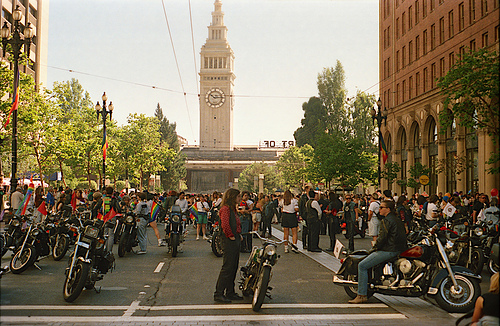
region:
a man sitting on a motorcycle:
[326, 198, 485, 315]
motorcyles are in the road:
[5, 179, 464, 315]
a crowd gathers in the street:
[11, 160, 491, 301]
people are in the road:
[6, 169, 488, 310]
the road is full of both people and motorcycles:
[9, 178, 491, 307]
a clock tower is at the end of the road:
[181, 0, 250, 159]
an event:
[5, 141, 495, 324]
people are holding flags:
[21, 174, 228, 255]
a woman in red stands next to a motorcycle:
[204, 183, 294, 312]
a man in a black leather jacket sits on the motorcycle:
[334, 199, 479, 311]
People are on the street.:
[15, 163, 498, 250]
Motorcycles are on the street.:
[1, 205, 498, 320]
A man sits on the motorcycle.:
[319, 191, 484, 308]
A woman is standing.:
[192, 182, 266, 309]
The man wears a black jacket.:
[363, 207, 416, 257]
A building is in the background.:
[140, 1, 331, 207]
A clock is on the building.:
[190, 79, 230, 116]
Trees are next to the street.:
[0, 55, 400, 214]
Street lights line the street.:
[80, 82, 126, 199]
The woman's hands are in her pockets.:
[217, 220, 254, 253]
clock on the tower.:
[208, 90, 223, 110]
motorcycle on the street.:
[250, 240, 283, 304]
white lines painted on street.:
[142, 299, 198, 316]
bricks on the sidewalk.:
[292, 321, 332, 324]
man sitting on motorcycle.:
[365, 215, 400, 295]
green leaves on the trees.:
[59, 117, 89, 165]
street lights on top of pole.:
[0, 7, 25, 42]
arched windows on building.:
[421, 115, 437, 169]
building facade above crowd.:
[404, 24, 469, 51]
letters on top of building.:
[262, 135, 293, 152]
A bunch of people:
[5, 112, 499, 322]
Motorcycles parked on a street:
[7, 164, 499, 313]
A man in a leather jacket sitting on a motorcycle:
[333, 199, 464, 309]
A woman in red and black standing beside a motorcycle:
[212, 184, 286, 311]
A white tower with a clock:
[192, 4, 250, 163]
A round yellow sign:
[414, 170, 436, 192]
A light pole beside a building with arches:
[365, 12, 440, 196]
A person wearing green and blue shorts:
[192, 192, 212, 248]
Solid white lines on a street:
[0, 293, 384, 324]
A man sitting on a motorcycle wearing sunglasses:
[325, 193, 472, 324]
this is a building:
[193, 15, 239, 150]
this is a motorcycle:
[242, 231, 293, 306]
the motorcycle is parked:
[236, 245, 282, 311]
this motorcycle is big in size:
[58, 217, 123, 299]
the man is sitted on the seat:
[353, 193, 408, 304]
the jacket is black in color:
[378, 217, 400, 251]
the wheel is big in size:
[250, 263, 275, 304]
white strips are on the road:
[144, 292, 206, 323]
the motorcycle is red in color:
[409, 243, 424, 254]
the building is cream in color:
[192, 2, 233, 150]